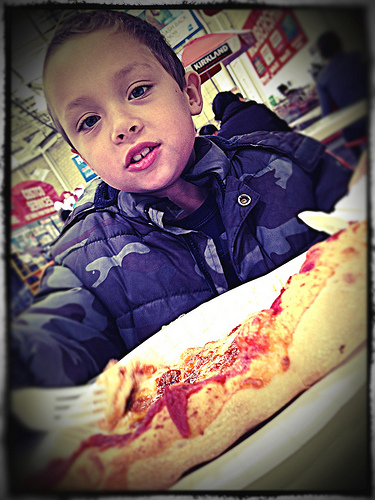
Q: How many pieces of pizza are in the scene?
A: One.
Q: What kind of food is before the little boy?
A: Pizza.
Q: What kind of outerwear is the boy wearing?
A: Coat.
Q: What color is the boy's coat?
A: Blue.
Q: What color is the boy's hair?
A: Brown.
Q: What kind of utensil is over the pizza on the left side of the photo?
A: Fork.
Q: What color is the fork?
A: White.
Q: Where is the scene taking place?
A: Inside a store that sells pizza.